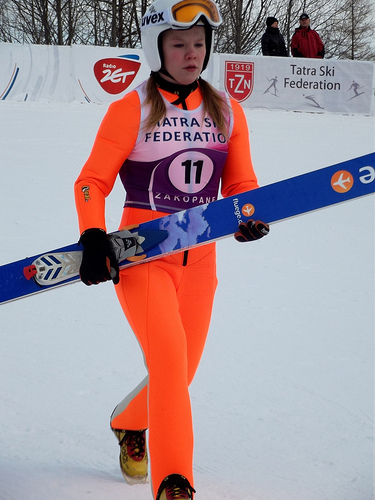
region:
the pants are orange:
[135, 336, 195, 468]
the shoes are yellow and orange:
[115, 436, 151, 484]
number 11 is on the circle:
[174, 155, 217, 186]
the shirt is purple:
[129, 158, 227, 215]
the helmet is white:
[142, 8, 169, 68]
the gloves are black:
[76, 233, 121, 281]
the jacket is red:
[292, 28, 330, 56]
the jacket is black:
[256, 29, 290, 57]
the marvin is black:
[262, 15, 280, 25]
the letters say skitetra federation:
[278, 62, 344, 95]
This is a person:
[287, 5, 328, 66]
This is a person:
[260, 3, 286, 76]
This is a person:
[76, 0, 276, 497]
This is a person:
[186, 375, 189, 402]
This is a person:
[154, 26, 281, 323]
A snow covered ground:
[255, 368, 340, 468]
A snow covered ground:
[2, 462, 101, 495]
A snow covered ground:
[216, 314, 283, 383]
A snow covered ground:
[294, 272, 352, 365]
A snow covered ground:
[2, 311, 94, 371]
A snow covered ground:
[11, 119, 75, 185]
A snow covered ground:
[259, 130, 348, 161]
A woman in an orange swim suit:
[132, 17, 243, 362]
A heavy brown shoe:
[105, 414, 151, 478]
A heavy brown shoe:
[147, 477, 194, 499]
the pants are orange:
[72, 296, 208, 452]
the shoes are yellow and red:
[119, 436, 152, 480]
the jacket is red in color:
[292, 30, 327, 56]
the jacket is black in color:
[256, 30, 287, 54]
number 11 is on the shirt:
[167, 152, 217, 199]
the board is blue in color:
[255, 169, 333, 219]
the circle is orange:
[330, 170, 357, 198]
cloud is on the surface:
[166, 213, 217, 243]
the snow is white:
[240, 465, 357, 490]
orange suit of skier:
[74, 79, 281, 477]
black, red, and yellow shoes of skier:
[112, 418, 192, 498]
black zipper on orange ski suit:
[174, 95, 192, 272]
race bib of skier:
[122, 82, 231, 213]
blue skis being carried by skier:
[1, 137, 373, 310]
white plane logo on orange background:
[330, 170, 353, 193]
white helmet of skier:
[134, 1, 220, 68]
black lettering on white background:
[138, 9, 165, 28]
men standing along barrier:
[258, 9, 329, 53]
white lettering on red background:
[226, 73, 253, 97]